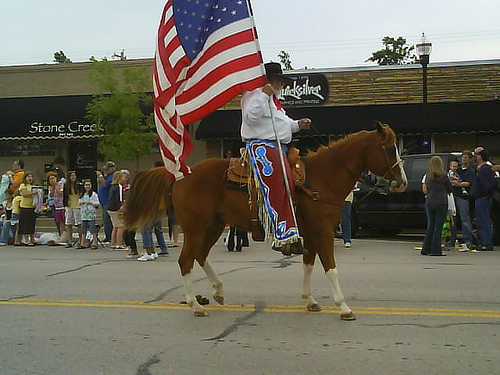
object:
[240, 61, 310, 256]
man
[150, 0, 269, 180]
flag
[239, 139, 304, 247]
pants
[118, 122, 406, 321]
horse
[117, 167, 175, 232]
tail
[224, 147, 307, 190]
saddle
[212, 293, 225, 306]
hooves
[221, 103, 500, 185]
store fronts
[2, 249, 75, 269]
street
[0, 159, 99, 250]
audience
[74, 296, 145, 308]
lines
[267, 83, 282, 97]
facial hair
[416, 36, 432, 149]
light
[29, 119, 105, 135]
stone creek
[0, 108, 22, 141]
awning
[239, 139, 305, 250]
chaps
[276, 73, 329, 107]
sign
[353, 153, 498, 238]
car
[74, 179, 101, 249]
girl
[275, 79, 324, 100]
lettering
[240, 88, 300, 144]
shirt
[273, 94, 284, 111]
tie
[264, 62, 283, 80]
hat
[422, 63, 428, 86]
pole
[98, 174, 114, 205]
jacket